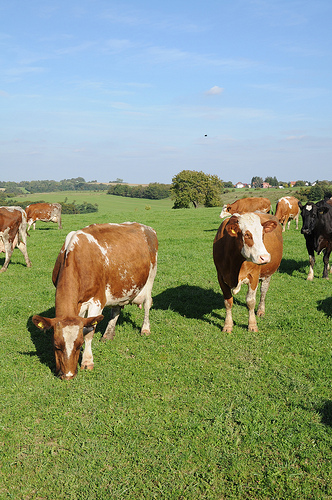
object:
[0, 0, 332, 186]
sky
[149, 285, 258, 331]
shadow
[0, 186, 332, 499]
ground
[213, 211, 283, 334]
cow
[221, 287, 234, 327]
leg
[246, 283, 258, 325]
leg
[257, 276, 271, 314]
leg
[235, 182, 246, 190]
buildings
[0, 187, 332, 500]
grass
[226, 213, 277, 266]
head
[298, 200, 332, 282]
cow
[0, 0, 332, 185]
clouds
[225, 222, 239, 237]
ear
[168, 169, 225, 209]
trees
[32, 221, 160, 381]
cow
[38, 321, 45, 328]
tag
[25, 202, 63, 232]
cattle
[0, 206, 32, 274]
cattle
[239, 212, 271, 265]
face